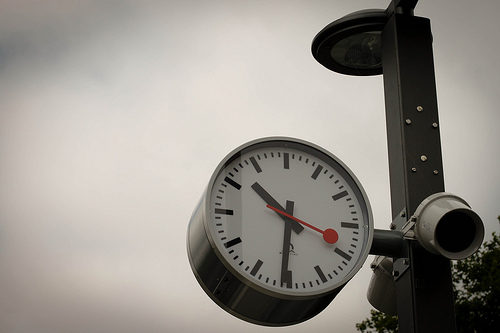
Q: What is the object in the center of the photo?
A: Clock.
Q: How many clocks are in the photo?
A: One.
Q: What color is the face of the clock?
A: Black and white.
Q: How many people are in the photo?
A: None.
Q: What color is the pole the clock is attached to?
A: Black.